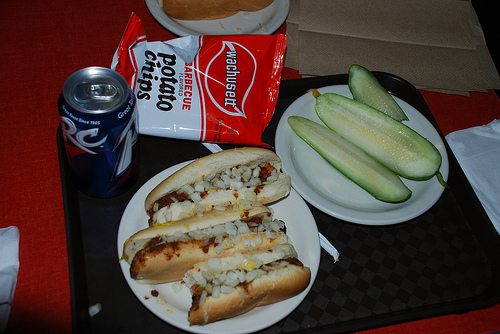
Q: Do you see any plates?
A: Yes, there is a plate.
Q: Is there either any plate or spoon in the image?
A: Yes, there is a plate.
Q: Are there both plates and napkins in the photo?
A: Yes, there are both a plate and a napkin.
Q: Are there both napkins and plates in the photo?
A: Yes, there are both a plate and a napkin.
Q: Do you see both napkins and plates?
A: Yes, there are both a plate and a napkin.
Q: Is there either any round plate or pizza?
A: Yes, there is a round plate.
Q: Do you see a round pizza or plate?
A: Yes, there is a round plate.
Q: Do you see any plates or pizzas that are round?
A: Yes, the plate is round.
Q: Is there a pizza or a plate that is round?
A: Yes, the plate is round.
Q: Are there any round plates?
A: Yes, there is a round plate.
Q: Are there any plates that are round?
A: Yes, there is a plate that is round.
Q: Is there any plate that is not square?
A: Yes, there is a round plate.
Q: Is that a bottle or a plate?
A: That is a plate.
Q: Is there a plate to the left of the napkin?
A: Yes, there is a plate to the left of the napkin.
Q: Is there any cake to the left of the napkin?
A: No, there is a plate to the left of the napkin.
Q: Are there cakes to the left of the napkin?
A: No, there is a plate to the left of the napkin.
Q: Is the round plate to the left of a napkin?
A: Yes, the plate is to the left of a napkin.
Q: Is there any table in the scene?
A: Yes, there is a table.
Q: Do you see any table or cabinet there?
A: Yes, there is a table.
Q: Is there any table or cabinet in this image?
A: Yes, there is a table.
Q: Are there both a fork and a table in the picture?
A: No, there is a table but no forks.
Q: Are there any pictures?
A: No, there are no pictures.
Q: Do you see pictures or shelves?
A: No, there are no pictures or shelves.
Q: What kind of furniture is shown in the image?
A: The furniture is a table.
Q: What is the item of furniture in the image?
A: The piece of furniture is a table.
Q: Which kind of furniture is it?
A: The piece of furniture is a table.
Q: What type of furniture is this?
A: That is a table.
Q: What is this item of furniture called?
A: That is a table.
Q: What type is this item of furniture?
A: That is a table.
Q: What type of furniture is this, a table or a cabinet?
A: That is a table.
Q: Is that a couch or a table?
A: That is a table.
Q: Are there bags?
A: Yes, there is a bag.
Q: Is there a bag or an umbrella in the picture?
A: Yes, there is a bag.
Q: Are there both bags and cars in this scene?
A: No, there is a bag but no cars.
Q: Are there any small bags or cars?
A: Yes, there is a small bag.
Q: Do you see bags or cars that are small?
A: Yes, the bag is small.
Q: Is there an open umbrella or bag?
A: Yes, there is an open bag.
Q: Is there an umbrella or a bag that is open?
A: Yes, the bag is open.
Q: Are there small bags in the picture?
A: Yes, there is a small bag.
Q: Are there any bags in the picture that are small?
A: Yes, there is a bag that is small.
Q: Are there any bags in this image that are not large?
A: Yes, there is a small bag.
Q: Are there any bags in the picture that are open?
A: Yes, there is an open bag.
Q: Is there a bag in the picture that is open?
A: Yes, there is a bag that is open.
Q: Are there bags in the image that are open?
A: Yes, there is a bag that is open.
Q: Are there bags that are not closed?
A: Yes, there is a open bag.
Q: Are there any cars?
A: No, there are no cars.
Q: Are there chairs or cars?
A: No, there are no cars or chairs.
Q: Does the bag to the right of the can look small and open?
A: Yes, the bag is small and open.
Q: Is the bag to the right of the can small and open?
A: Yes, the bag is small and open.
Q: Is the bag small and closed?
A: No, the bag is small but open.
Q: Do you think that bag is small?
A: Yes, the bag is small.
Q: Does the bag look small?
A: Yes, the bag is small.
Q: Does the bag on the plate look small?
A: Yes, the bag is small.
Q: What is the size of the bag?
A: The bag is small.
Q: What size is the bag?
A: The bag is small.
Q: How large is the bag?
A: The bag is small.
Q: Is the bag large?
A: No, the bag is small.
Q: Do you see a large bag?
A: No, there is a bag but it is small.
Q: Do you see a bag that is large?
A: No, there is a bag but it is small.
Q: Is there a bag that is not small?
A: No, there is a bag but it is small.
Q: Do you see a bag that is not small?
A: No, there is a bag but it is small.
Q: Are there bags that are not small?
A: No, there is a bag but it is small.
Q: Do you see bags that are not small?
A: No, there is a bag but it is small.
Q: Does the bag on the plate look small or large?
A: The bag is small.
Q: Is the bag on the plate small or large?
A: The bag is small.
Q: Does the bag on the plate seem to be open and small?
A: Yes, the bag is open and small.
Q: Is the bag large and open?
A: No, the bag is open but small.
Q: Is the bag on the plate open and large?
A: No, the bag is open but small.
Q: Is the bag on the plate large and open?
A: No, the bag is open but small.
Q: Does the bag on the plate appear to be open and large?
A: No, the bag is open but small.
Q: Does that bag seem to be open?
A: Yes, the bag is open.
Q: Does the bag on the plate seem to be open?
A: Yes, the bag is open.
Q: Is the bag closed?
A: No, the bag is open.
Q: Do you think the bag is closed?
A: No, the bag is open.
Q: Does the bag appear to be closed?
A: No, the bag is open.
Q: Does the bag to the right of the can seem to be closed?
A: No, the bag is open.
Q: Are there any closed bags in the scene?
A: No, there is a bag but it is open.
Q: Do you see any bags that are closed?
A: No, there is a bag but it is open.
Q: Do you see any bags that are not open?
A: No, there is a bag but it is open.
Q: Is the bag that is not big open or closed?
A: The bag is open.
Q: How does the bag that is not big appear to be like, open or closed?
A: The bag is open.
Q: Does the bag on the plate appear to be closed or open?
A: The bag is open.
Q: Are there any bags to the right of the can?
A: Yes, there is a bag to the right of the can.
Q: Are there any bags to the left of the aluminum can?
A: No, the bag is to the right of the can.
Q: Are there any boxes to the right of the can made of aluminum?
A: No, there is a bag to the right of the can.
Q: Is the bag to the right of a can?
A: Yes, the bag is to the right of a can.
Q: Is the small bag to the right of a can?
A: Yes, the bag is to the right of a can.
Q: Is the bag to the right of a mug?
A: No, the bag is to the right of a can.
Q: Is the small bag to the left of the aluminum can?
A: No, the bag is to the right of the can.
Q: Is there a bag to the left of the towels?
A: Yes, there is a bag to the left of the towels.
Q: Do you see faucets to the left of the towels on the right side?
A: No, there is a bag to the left of the towels.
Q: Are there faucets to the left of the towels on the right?
A: No, there is a bag to the left of the towels.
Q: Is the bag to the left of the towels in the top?
A: Yes, the bag is to the left of the towels.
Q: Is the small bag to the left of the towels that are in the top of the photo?
A: Yes, the bag is to the left of the towels.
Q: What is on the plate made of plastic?
A: The bag is on the plate.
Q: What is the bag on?
A: The bag is on the plate.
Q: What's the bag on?
A: The bag is on the plate.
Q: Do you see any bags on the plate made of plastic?
A: Yes, there is a bag on the plate.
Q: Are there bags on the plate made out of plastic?
A: Yes, there is a bag on the plate.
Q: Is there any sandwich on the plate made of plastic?
A: No, there is a bag on the plate.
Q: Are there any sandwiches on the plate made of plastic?
A: No, there is a bag on the plate.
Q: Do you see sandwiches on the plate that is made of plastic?
A: No, there is a bag on the plate.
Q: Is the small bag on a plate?
A: Yes, the bag is on a plate.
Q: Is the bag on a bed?
A: No, the bag is on a plate.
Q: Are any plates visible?
A: Yes, there is a plate.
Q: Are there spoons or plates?
A: Yes, there is a plate.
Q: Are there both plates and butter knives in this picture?
A: No, there is a plate but no butter knives.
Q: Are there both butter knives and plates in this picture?
A: No, there is a plate but no butter knives.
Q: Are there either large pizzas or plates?
A: Yes, there is a large plate.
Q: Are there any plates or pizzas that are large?
A: Yes, the plate is large.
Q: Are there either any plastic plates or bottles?
A: Yes, there is a plastic plate.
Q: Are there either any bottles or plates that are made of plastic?
A: Yes, the plate is made of plastic.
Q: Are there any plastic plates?
A: Yes, there is a plate that is made of plastic.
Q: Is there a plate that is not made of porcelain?
A: Yes, there is a plate that is made of plastic.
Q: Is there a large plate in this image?
A: Yes, there is a large plate.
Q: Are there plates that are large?
A: Yes, there is a plate that is large.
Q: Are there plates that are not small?
A: Yes, there is a large plate.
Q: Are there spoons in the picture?
A: No, there are no spoons.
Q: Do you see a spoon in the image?
A: No, there are no spoons.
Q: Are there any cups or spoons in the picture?
A: No, there are no spoons or cups.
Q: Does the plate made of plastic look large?
A: Yes, the plate is large.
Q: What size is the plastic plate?
A: The plate is large.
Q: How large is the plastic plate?
A: The plate is large.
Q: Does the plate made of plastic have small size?
A: No, the plate is large.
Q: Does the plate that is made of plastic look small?
A: No, the plate is large.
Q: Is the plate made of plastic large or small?
A: The plate is large.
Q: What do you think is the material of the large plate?
A: The plate is made of plastic.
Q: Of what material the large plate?
A: The plate is made of plastic.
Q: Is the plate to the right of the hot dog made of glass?
A: No, the plate is made of plastic.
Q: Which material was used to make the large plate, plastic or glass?
A: The plate is made of plastic.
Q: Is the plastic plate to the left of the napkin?
A: Yes, the plate is to the left of the napkin.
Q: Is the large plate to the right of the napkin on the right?
A: No, the plate is to the left of the napkin.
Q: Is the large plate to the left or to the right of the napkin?
A: The plate is to the left of the napkin.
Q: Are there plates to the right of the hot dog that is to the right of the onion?
A: Yes, there is a plate to the right of the hot dog.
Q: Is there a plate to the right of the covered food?
A: Yes, there is a plate to the right of the hot dog.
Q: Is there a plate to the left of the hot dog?
A: No, the plate is to the right of the hot dog.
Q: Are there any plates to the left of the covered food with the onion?
A: No, the plate is to the right of the hot dog.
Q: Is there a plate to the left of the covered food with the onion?
A: No, the plate is to the right of the hot dog.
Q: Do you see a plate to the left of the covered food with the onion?
A: No, the plate is to the right of the hot dog.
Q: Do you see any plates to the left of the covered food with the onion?
A: No, the plate is to the right of the hot dog.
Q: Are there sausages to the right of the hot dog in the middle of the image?
A: No, there is a plate to the right of the hot dog.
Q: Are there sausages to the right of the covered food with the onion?
A: No, there is a plate to the right of the hot dog.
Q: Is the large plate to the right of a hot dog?
A: Yes, the plate is to the right of a hot dog.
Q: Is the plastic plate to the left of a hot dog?
A: No, the plate is to the right of a hot dog.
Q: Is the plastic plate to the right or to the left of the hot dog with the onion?
A: The plate is to the right of the hot dog.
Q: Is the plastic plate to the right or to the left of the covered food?
A: The plate is to the right of the hot dog.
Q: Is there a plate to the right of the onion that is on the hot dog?
A: Yes, there is a plate to the right of the onion.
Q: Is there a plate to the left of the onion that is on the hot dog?
A: No, the plate is to the right of the onion.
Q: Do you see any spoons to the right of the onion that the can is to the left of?
A: No, there is a plate to the right of the onion.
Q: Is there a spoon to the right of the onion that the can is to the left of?
A: No, there is a plate to the right of the onion.